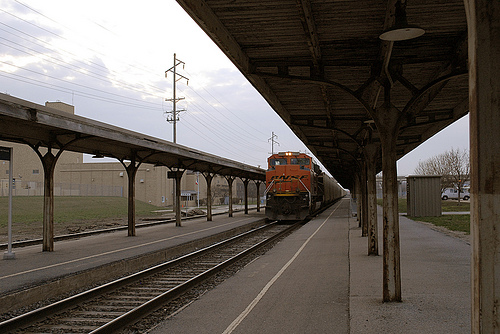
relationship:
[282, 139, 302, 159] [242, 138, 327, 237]
light on train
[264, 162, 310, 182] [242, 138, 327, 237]
letters on train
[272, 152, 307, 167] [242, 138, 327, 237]
window of train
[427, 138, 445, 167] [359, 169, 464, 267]
tree next to parking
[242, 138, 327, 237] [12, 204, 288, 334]
train on tracks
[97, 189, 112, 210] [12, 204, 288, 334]
grass by tracks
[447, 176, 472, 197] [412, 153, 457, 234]
vehicle in background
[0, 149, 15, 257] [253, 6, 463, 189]
pole on bridge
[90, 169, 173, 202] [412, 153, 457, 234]
building in background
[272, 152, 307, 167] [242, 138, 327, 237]
window on train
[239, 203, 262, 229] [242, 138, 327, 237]
gravel on side of train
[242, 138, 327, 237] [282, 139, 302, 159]
train has light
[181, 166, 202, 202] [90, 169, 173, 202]
fence around building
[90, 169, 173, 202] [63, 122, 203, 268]
building on side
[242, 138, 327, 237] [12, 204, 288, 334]
train has tracks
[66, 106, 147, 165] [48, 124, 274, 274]
roof of station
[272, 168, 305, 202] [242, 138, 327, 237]
front of train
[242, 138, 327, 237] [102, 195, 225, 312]
train has platform